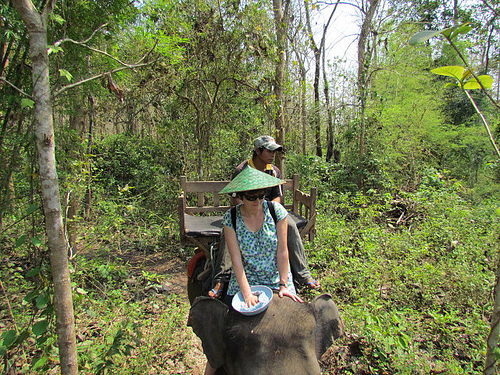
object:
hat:
[217, 164, 287, 194]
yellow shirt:
[229, 157, 284, 202]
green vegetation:
[0, 0, 500, 375]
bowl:
[230, 285, 274, 316]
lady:
[218, 165, 304, 302]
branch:
[459, 89, 500, 155]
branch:
[359, 108, 366, 159]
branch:
[50, 66, 130, 100]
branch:
[47, 21, 111, 55]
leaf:
[20, 97, 36, 110]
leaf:
[30, 316, 54, 337]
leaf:
[1, 326, 20, 348]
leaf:
[25, 268, 41, 278]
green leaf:
[429, 65, 465, 83]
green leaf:
[463, 74, 494, 90]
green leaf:
[408, 26, 451, 46]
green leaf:
[449, 25, 473, 40]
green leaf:
[58, 68, 74, 83]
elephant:
[185, 278, 344, 375]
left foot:
[299, 271, 322, 290]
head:
[242, 187, 268, 211]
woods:
[73, 52, 96, 61]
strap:
[230, 206, 237, 231]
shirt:
[220, 199, 297, 296]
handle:
[252, 291, 263, 303]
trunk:
[272, 23, 288, 179]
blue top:
[219, 198, 297, 296]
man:
[206, 133, 321, 301]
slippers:
[304, 278, 320, 290]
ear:
[307, 291, 345, 363]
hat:
[252, 135, 283, 152]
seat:
[176, 172, 319, 243]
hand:
[244, 293, 259, 308]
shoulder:
[222, 203, 244, 223]